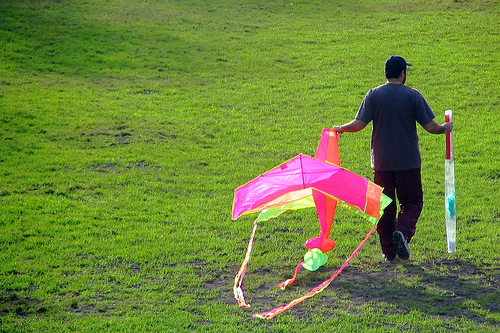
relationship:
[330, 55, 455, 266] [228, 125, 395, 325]
man dragging kite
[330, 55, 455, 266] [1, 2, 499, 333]
man walking through grass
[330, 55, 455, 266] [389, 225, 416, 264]
man inside of sneaker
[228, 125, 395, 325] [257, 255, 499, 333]
kite has shadow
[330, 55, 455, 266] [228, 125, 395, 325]
man carrying kite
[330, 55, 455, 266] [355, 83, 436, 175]
man inside of a t-shirt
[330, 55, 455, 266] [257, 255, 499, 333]
man has shadow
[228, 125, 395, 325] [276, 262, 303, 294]
kite has tassel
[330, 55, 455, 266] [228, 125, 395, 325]
man flying kite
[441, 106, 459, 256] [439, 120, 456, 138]
something held in hand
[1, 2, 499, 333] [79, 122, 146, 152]
grass has part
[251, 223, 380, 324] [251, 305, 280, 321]
ribbon has part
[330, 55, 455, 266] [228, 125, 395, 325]
man with kite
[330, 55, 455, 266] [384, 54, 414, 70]
man wearing cap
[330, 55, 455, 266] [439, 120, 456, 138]
man has hand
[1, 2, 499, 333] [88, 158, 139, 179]
grass has patch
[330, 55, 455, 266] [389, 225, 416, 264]
man wearing sneaker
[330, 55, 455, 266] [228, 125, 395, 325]
man has kite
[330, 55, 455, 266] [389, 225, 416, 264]
man has sneaker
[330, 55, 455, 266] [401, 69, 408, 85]
man has beard